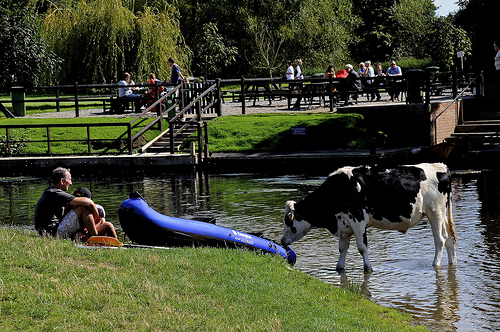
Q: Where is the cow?
A: In the stream.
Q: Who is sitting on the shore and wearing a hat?
A: Person behind the man in the foreground.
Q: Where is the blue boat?
A: To the left of the cow.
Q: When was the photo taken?
A: Daytime.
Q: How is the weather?
A: Sunny.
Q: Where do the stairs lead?
A: To a picnic area.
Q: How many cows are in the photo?
A: 1.